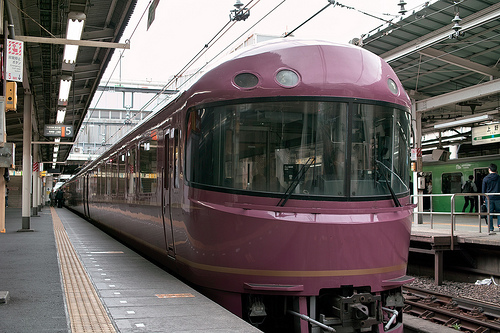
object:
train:
[50, 38, 422, 332]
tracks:
[393, 284, 500, 331]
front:
[176, 36, 415, 294]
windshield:
[180, 98, 416, 202]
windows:
[92, 130, 159, 215]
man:
[481, 160, 500, 232]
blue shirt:
[482, 173, 500, 193]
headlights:
[231, 62, 415, 104]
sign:
[6, 36, 26, 84]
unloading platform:
[2, 198, 268, 331]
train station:
[2, 1, 499, 332]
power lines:
[61, 0, 408, 190]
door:
[153, 120, 182, 255]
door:
[80, 172, 92, 223]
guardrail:
[416, 189, 500, 240]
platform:
[409, 208, 498, 244]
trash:
[472, 271, 500, 288]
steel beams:
[21, 77, 47, 229]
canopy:
[3, 1, 140, 188]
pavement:
[1, 201, 67, 331]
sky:
[96, 0, 436, 87]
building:
[419, 155, 500, 216]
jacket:
[481, 171, 499, 211]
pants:
[484, 199, 499, 230]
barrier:
[50, 200, 114, 332]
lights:
[50, 12, 88, 176]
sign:
[471, 121, 500, 144]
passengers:
[47, 185, 66, 208]